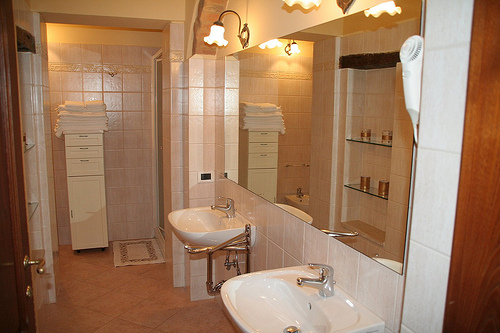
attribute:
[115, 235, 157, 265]
rug — small, white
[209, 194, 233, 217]
faucet — silver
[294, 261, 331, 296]
faucet — silver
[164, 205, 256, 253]
sink — white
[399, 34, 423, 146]
air freshener — white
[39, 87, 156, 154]
towel — white, folded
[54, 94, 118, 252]
cabinet — eggshell colored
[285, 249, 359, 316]
faucett — stainless steel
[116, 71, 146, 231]
tile wall — tiled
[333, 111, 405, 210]
bottles — reflected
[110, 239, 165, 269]
rug — beige, tan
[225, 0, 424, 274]
mirror — large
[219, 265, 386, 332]
sink — white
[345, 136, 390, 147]
shelve — glass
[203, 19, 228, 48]
light fixture — flower shaped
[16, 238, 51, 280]
door handle — brass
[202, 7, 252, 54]
light fixture — lit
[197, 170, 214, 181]
outlet — electrical 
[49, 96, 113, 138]
towels — white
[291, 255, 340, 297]
faucet — silver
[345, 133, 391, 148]
shelf — glass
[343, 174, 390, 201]
shelf — glass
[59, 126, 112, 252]
cabinet — white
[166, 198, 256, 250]
sink — white